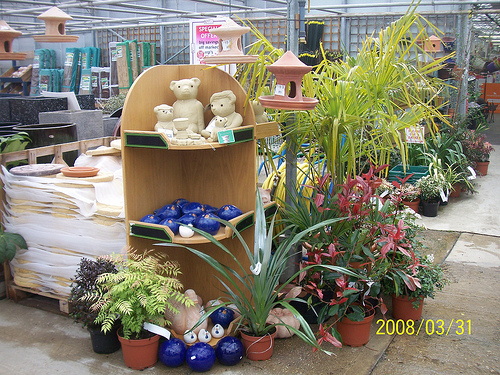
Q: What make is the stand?
A: Wood.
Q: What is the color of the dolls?
A: White.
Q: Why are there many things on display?
A: They are for sale.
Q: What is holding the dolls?
A: Stand.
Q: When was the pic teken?
A: 2008/03/31.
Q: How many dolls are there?
A: 4.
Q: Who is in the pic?
A: No one.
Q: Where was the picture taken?
A: On the street.